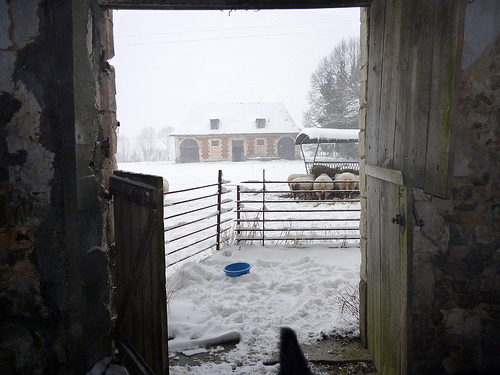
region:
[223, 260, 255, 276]
bright blue animal food dish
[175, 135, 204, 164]
arched shaped window with grey brick trim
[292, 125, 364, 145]
curved metal roof of feeding trough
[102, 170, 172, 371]
dark grey wooden barn door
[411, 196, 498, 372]
small section of grey stone barn wall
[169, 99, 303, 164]
small red and tan brick farm house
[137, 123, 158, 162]
tall bare tree covered in snow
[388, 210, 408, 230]
small black wrought iron door latch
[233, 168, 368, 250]
brown section of metal fence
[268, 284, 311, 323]
snow on the ground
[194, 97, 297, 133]
snow on the roof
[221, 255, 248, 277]
bowl in the snow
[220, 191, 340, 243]
metal on the fence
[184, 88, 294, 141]
roof of the house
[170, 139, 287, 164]
front of the house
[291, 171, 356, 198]
the sheep are eating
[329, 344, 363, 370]
no snow on ground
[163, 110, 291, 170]
a house in the back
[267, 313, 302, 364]
a part of the stone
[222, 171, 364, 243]
a gate in the fence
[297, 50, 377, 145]
a part of the tree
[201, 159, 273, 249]
a small gate in the ice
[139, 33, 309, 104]
a beautiful white sky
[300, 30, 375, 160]
a part of large tree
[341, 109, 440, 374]
a small in the home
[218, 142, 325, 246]
fence next to the snow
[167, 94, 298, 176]
house in the distance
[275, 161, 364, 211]
animals next to fence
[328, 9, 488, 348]
door in the photo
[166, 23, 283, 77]
sky above the land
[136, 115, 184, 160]
trees in the distance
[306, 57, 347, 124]
branches on the tree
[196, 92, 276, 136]
roof of the building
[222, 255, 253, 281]
blue pail in the snow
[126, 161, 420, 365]
gates to building that are open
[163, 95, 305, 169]
home behind the sheep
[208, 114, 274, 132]
chimneys on the roof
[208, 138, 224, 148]
window to the home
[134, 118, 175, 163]
bare trees without leaves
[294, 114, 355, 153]
covering over the feed area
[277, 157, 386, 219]
Several animals feeding from the trough in the snow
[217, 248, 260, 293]
Dog bowl laying in the snow near the barn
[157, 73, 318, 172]
brick house in front of the trough with the animals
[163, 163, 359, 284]
Fencing in front of the barn in the snow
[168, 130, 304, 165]
two doors on the house in the back yard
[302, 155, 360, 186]
Hay in the trough for the sheep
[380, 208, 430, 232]
Knob in the door at the entry way to the barn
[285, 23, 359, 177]
Large tree to the right of the house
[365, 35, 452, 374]
a open wood door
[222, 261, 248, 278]
a blue plastic bucket on the ground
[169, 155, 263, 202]
the ground covered with snow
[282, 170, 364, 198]
four sheep at a troft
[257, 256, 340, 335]
tracks in the snow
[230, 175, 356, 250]
a metal fence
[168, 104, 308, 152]
a roof of a house covered with snow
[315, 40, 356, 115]
a tree with no leaves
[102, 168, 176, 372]
a half wood door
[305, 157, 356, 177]
hay in a feed troft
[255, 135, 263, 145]
glass window on the building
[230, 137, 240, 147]
glass window on the building